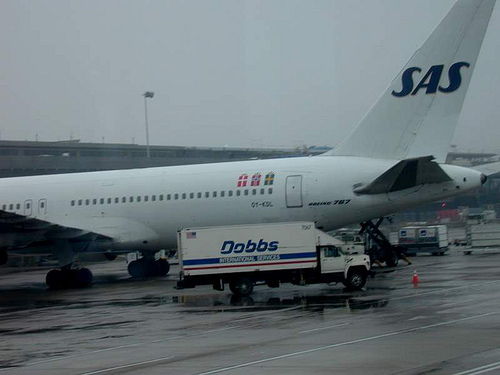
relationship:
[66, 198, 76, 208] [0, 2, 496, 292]
window on airplane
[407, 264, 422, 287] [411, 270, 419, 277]
cone with stripes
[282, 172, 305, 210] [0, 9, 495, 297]
door of plane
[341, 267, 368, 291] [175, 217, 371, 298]
tire on truck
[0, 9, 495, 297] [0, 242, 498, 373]
plane in runway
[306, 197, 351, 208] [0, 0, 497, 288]
emblem of boeing 787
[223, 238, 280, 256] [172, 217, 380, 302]
blue writing on truck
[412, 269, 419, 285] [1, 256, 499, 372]
cone on tarmac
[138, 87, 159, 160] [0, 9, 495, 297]
pole behind plane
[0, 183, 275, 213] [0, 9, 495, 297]
windows on plane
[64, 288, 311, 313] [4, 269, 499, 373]
water on runway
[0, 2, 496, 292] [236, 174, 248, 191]
airplane with logo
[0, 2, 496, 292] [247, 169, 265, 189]
airplane with logo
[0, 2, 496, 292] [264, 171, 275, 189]
airplane with logo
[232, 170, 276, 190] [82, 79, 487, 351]
presents on side plane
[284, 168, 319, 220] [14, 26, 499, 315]
door on plane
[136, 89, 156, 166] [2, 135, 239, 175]
pole on building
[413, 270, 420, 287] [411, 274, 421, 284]
person wear red shirt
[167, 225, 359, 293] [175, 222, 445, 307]
stripes on truck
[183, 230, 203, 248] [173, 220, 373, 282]
american flag on truck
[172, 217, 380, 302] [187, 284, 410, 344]
truck on tarmac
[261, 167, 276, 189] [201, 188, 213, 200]
flag above plane window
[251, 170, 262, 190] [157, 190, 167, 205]
flag above plane window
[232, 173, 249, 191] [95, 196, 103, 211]
flag above plane window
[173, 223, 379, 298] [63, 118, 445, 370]
truck at airport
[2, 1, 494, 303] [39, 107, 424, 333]
aeroplane on airport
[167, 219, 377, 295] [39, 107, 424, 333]
truck on airport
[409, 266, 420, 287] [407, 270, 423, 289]
lady in dress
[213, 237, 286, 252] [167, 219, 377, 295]
dobbs on side truck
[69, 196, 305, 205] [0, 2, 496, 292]
windows on airplane